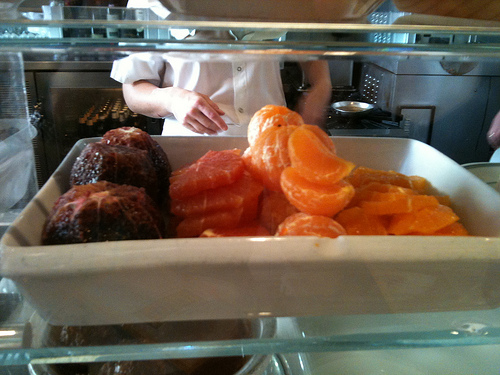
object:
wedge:
[276, 211, 346, 239]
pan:
[0, 131, 499, 328]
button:
[237, 67, 243, 71]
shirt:
[109, 52, 292, 136]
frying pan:
[332, 101, 375, 114]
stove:
[328, 122, 402, 135]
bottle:
[85, 119, 94, 137]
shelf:
[31, 331, 499, 361]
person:
[110, 46, 333, 136]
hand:
[168, 88, 229, 136]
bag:
[28, 22, 53, 36]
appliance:
[393, 50, 490, 143]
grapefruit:
[172, 150, 245, 196]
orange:
[366, 189, 432, 215]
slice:
[179, 195, 235, 216]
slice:
[277, 212, 346, 238]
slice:
[254, 108, 275, 130]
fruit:
[41, 180, 160, 239]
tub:
[0, 120, 35, 224]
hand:
[296, 104, 327, 125]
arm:
[108, 57, 165, 118]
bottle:
[116, 100, 122, 103]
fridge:
[39, 74, 108, 110]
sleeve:
[107, 59, 163, 83]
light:
[412, 148, 429, 160]